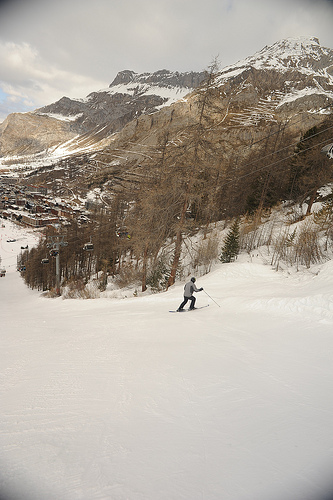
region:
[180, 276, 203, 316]
a person skiing down a slope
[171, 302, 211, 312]
a pair of skis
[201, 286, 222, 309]
a ski pole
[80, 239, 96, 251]
a car on a ski lift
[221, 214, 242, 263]
pine tree on the side of the mountain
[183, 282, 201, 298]
gray and white jacket a skiier is wearing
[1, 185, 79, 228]
buildings near the ski slope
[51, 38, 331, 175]
mountain peaks behind the slopes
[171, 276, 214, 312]
a solitary person skiing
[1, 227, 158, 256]
ski lift carrying skiiers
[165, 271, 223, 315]
person skiing in snow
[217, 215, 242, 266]
evergreen tree growing outside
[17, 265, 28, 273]
people riding on ski lift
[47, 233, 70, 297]
large metal ski lift support pole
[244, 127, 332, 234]
large brown colored trees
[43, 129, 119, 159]
white snow on mountain slope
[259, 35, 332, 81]
top of mountain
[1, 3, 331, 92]
grey clouds in sky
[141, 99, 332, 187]
wire cable for ski lift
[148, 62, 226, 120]
steep rocky mountain slope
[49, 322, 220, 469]
the snow is white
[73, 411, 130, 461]
the snow is white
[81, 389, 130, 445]
the snow is white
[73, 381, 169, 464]
the snow is white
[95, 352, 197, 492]
the snow is white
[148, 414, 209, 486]
the snow is white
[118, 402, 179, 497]
the snow is white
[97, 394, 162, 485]
the snow is white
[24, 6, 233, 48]
the sky is gray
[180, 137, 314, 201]
the wires are long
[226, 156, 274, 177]
the wires are thin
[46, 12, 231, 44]
the sky is dreary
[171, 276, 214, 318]
the man is skiing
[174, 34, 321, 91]
the mountain is sloped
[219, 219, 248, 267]
the tree is small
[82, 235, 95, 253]
the carriage on wire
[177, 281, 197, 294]
the jacket is gray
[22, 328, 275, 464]
the ground is covered in snow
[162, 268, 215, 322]
The person is skiing.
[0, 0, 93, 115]
The sky is overcast.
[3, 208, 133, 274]
A ski lift.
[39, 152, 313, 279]
A small forest.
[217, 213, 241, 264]
A pine tree.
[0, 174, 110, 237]
A small city at the bottom of the mountain.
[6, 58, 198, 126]
A mountain range.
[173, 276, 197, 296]
The person is wearing a gray jacket.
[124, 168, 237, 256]
Many of the trees have lost their leaves.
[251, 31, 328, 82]
A snow covered mountain peak.